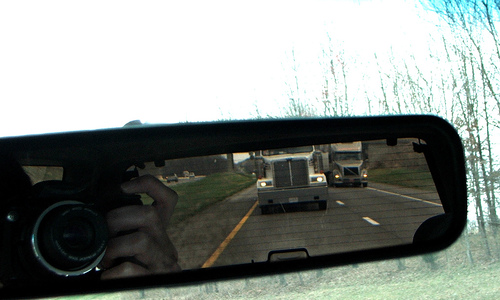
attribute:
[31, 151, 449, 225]
mirror — black, rectangle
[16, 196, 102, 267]
camera — black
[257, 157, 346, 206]
semi truck — white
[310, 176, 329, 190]
light — on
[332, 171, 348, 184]
light — on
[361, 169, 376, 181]
light — on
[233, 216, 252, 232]
stripe — yellow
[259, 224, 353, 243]
road — black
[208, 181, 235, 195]
grass — green